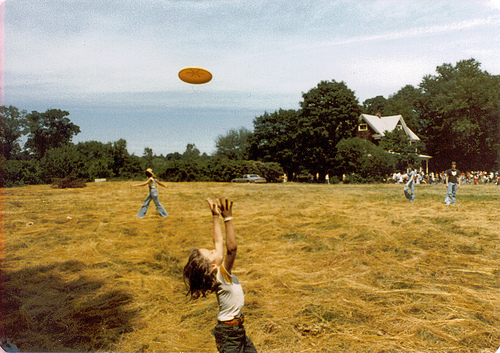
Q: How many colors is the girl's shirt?
A: One.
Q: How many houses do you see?
A: One.